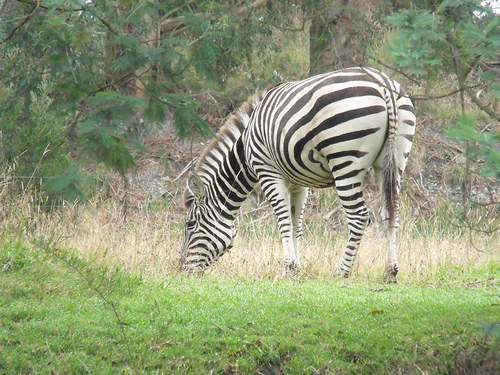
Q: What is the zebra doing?
A: Grazing.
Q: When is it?
A: Daytime.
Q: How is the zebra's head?
A: Down towards the ground.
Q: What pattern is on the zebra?
A: Stripes.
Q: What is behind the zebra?
A: Trees.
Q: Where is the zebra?
A: Standing on the grass.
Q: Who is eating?
A: The zebra.